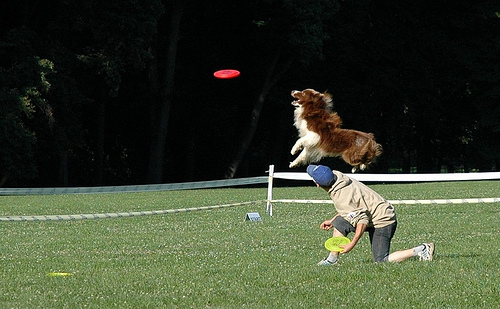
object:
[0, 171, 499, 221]
fence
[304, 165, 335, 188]
baseball cap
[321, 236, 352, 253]
frisbee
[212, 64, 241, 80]
frisbee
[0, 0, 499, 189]
air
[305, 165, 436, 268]
boy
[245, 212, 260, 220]
placard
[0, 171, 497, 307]
grassy area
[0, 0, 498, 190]
background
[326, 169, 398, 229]
jacket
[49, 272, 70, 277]
frisbee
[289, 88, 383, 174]
dog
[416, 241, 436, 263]
sneakers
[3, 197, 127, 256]
ground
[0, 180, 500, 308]
grass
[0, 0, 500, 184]
tree